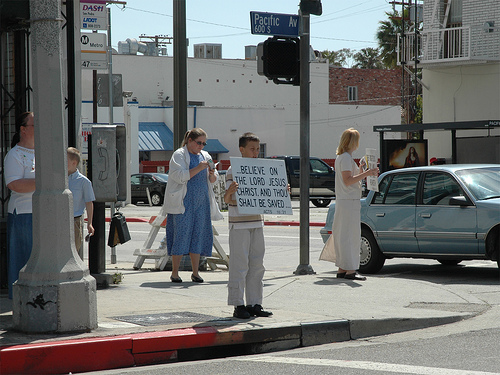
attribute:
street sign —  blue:
[248, 9, 301, 38]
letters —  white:
[252, 13, 300, 33]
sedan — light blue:
[320, 162, 499, 272]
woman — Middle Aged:
[161, 119, 221, 291]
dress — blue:
[168, 141, 218, 270]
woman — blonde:
[318, 126, 380, 280]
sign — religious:
[223, 152, 294, 219]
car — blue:
[301, 118, 498, 293]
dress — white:
[318, 152, 365, 272]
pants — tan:
[217, 207, 283, 325]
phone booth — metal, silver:
[89, 121, 124, 287]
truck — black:
[235, 118, 357, 233]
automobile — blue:
[320, 162, 497, 274]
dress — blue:
[167, 146, 223, 251]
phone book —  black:
[106, 207, 132, 249]